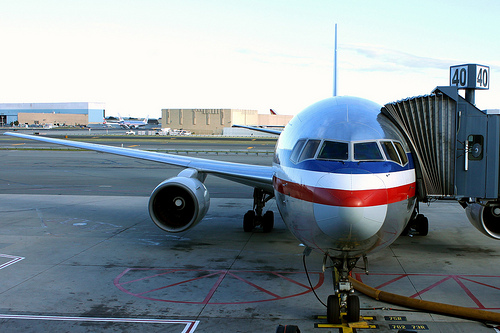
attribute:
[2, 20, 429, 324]
plane — striped, grey, here, parked, docked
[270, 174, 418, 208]
stripe — red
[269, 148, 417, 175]
stripe — blue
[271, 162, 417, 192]
stripe — white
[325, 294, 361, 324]
wheels — black, here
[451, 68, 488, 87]
numbers — black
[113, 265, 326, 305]
symbol — red, painted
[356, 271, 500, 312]
symbol — red, painted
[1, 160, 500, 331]
ground — black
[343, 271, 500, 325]
pipe — tannish brown, yellow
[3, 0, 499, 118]
sky — overcast, white, cloudy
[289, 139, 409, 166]
inside — dark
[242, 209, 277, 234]
wheels — here, black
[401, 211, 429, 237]
wheels — here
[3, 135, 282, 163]
runway — here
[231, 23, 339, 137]
tail — here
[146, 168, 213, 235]
engine — white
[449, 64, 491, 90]
sign — white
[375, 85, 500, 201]
skybridge — docked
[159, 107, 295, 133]
building — tan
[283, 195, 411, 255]
nose — grey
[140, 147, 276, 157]
railing — silver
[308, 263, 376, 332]
lines — yellow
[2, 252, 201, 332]
lines — white